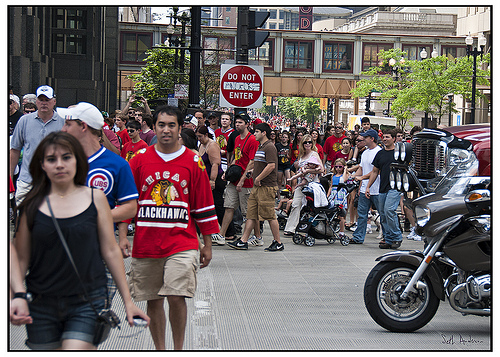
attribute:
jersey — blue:
[73, 149, 137, 229]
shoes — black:
[228, 238, 285, 253]